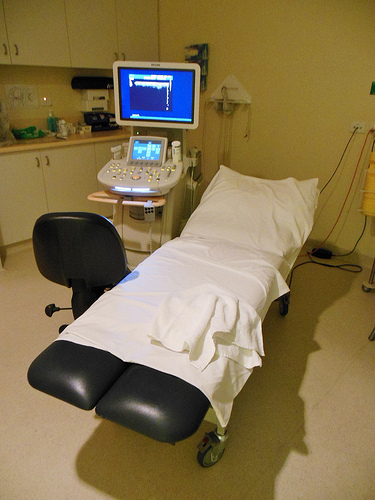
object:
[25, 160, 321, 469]
bed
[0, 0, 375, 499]
hospital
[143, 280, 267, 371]
towel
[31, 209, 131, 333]
chair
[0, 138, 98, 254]
cupboards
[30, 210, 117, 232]
bottom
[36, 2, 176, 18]
top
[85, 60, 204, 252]
medical equipment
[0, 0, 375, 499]
photo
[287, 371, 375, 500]
floor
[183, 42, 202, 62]
gloves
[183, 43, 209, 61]
box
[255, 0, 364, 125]
wall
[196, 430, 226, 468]
wheels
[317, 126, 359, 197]
cords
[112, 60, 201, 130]
monitor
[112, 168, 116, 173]
dials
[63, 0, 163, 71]
cabinets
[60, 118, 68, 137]
objects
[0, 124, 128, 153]
countertop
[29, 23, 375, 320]
office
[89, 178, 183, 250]
table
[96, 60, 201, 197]
computer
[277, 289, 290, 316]
wheel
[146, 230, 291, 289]
blankets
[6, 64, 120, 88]
side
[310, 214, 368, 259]
wires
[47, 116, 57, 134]
sanitizer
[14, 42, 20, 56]
handles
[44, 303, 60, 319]
knob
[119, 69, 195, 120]
screen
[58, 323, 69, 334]
wheel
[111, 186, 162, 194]
light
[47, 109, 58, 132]
bottle